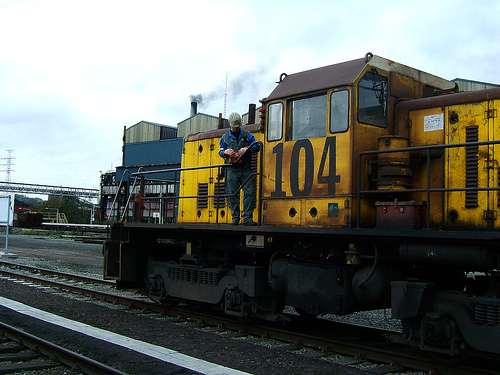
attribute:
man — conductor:
[221, 111, 262, 224]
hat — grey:
[230, 114, 241, 127]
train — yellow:
[108, 54, 499, 356]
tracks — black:
[4, 262, 500, 375]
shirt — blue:
[218, 132, 260, 168]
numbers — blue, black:
[271, 143, 341, 197]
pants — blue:
[226, 167, 254, 217]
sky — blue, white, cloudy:
[1, 2, 495, 192]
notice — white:
[425, 115, 442, 130]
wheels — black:
[140, 270, 492, 348]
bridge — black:
[1, 178, 99, 199]